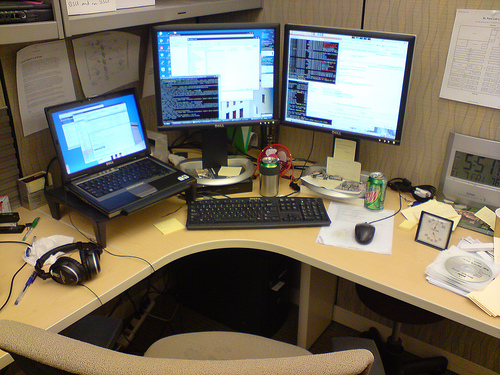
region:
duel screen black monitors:
[148, 26, 420, 145]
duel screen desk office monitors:
[144, 20, 411, 145]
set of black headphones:
[31, 238, 110, 285]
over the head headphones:
[32, 239, 104, 281]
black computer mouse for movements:
[351, 218, 378, 250]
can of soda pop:
[360, 167, 390, 209]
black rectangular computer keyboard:
[183, 193, 333, 232]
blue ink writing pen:
[15, 265, 40, 305]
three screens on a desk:
[35, 9, 422, 303]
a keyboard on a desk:
[181, 193, 332, 234]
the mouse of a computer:
[349, 215, 379, 247]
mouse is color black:
[348, 219, 379, 247]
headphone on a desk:
[25, 234, 115, 293]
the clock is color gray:
[438, 127, 499, 209]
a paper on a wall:
[431, 2, 499, 114]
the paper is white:
[431, 5, 499, 115]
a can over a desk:
[358, 165, 390, 214]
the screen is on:
[149, 22, 284, 133]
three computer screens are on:
[49, 20, 412, 167]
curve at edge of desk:
[128, 230, 313, 292]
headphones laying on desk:
[35, 237, 107, 282]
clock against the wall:
[440, 130, 497, 227]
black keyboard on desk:
[177, 193, 334, 235]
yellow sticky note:
[320, 133, 365, 168]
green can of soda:
[362, 168, 387, 213]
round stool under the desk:
[347, 278, 455, 371]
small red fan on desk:
[255, 137, 296, 179]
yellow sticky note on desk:
[152, 212, 184, 243]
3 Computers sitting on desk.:
[0, 1, 499, 373]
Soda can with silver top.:
[361, 170, 388, 214]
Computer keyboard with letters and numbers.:
[185, 192, 333, 229]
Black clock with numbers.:
[412, 207, 456, 251]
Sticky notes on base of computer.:
[145, 62, 285, 194]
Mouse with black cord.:
[348, 192, 419, 249]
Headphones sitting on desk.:
[0, 237, 499, 360]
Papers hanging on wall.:
[0, 2, 498, 139]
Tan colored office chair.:
[0, 314, 497, 372]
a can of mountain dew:
[363, 170, 388, 212]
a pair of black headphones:
[31, 238, 103, 289]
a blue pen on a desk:
[12, 271, 37, 309]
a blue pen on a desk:
[24, 232, 36, 260]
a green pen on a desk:
[22, 211, 42, 239]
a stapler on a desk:
[0, 211, 25, 234]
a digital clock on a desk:
[434, 130, 499, 211]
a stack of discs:
[421, 242, 496, 297]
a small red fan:
[246, 143, 301, 190]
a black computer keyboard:
[184, 190, 335, 231]